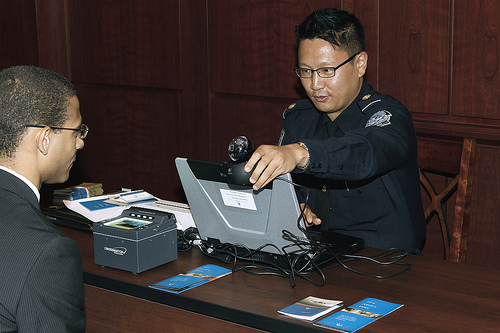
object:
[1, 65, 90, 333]
man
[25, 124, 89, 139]
glasses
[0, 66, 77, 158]
man hair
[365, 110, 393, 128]
badge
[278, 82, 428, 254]
shirt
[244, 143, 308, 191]
hand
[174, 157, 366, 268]
computer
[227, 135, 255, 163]
camera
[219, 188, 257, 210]
label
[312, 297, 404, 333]
pamphlets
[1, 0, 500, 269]
wall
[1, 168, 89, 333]
suit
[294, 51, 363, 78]
eyeglasses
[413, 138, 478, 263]
chair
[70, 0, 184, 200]
panelling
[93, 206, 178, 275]
box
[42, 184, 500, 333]
desk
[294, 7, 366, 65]
dark hair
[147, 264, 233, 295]
pamphlet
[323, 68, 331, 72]
eyes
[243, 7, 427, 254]
man